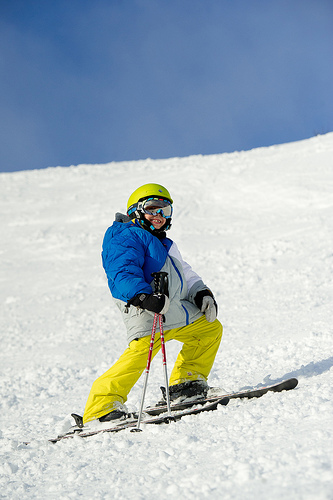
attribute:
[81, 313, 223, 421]
pants — yellow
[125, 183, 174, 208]
helmet — hard, yellow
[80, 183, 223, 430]
boy — young, smiling, skiing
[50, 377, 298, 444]
skis — black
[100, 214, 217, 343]
jacket — blue, grey, gray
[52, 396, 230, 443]
ski — long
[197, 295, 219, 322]
glove — black, white, gray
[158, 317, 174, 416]
pole — gray, red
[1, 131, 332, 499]
snow — white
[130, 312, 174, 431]
poles — silver, red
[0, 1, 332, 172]
sky — blue, clear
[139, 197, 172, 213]
goggles — blue